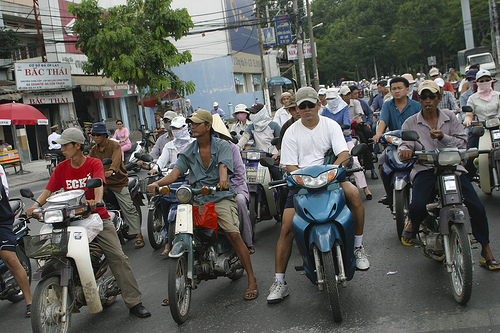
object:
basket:
[25, 231, 70, 260]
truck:
[454, 48, 496, 83]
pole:
[456, 2, 477, 50]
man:
[370, 75, 422, 204]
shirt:
[378, 97, 419, 129]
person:
[112, 120, 131, 161]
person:
[397, 79, 499, 272]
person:
[23, 127, 151, 319]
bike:
[396, 126, 496, 305]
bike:
[139, 180, 241, 323]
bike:
[12, 178, 106, 333]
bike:
[102, 140, 144, 172]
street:
[2, 104, 499, 333]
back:
[328, 45, 481, 94]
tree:
[65, 4, 199, 106]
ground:
[437, 147, 464, 170]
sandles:
[245, 283, 260, 300]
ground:
[356, 145, 369, 185]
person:
[463, 67, 499, 124]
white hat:
[473, 69, 494, 80]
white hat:
[166, 115, 185, 129]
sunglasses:
[476, 77, 491, 82]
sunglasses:
[420, 92, 435, 100]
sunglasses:
[297, 102, 314, 110]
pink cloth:
[476, 81, 495, 102]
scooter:
[15, 199, 130, 332]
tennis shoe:
[265, 281, 289, 303]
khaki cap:
[417, 80, 439, 96]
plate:
[0, 101, 49, 127]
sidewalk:
[2, 157, 49, 187]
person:
[83, 122, 145, 250]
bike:
[104, 175, 144, 245]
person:
[264, 85, 370, 303]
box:
[1, 144, 27, 175]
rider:
[143, 109, 256, 309]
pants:
[89, 218, 142, 308]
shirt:
[45, 153, 104, 218]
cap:
[52, 127, 84, 145]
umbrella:
[0, 101, 48, 125]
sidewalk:
[23, 160, 494, 331]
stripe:
[0, 156, 19, 163]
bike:
[258, 143, 371, 323]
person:
[235, 103, 280, 159]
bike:
[239, 143, 283, 237]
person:
[369, 76, 424, 143]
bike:
[366, 130, 406, 241]